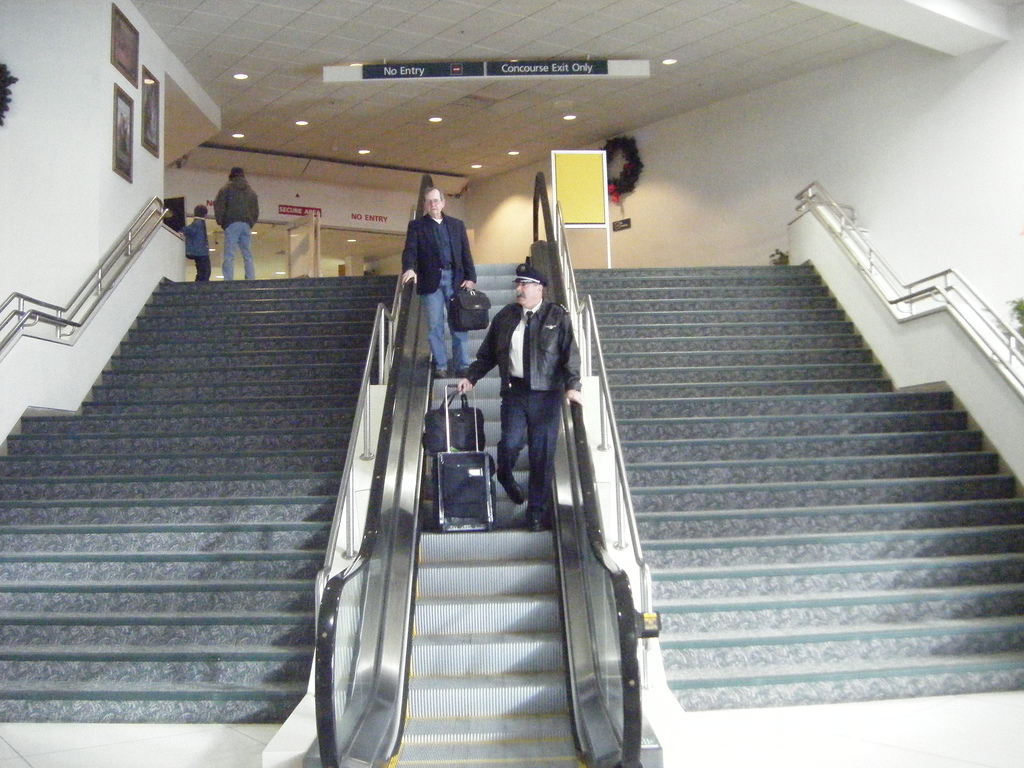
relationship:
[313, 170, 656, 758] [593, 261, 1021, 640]
escalator between stairs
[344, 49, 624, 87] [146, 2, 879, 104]
sign on ceiling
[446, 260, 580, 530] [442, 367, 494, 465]
man holding handle